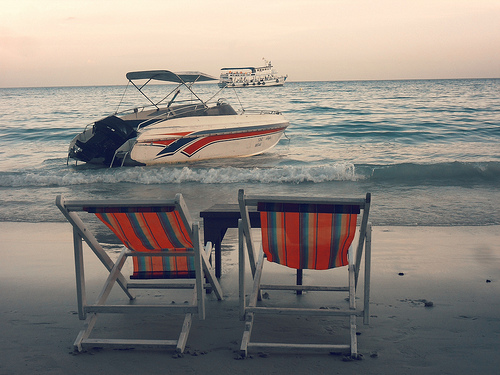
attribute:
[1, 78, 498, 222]
water — blue, calm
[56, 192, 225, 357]
chair — striped, iron, orange ad blue, stripes, empty, blue, orange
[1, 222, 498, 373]
sand — wet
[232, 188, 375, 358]
chair — striped, iron, orange ad blue, stripes, empty, blue, orange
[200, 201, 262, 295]
table — black, blue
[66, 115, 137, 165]
motor — black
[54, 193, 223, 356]
chair frame — white, metal, silver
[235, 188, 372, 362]
chair frame — white, metal, silver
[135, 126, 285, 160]
stripes — red, blue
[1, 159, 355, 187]
foam — white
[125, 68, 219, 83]
canopy — blue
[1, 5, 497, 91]
sky — pink, gray, gloomy